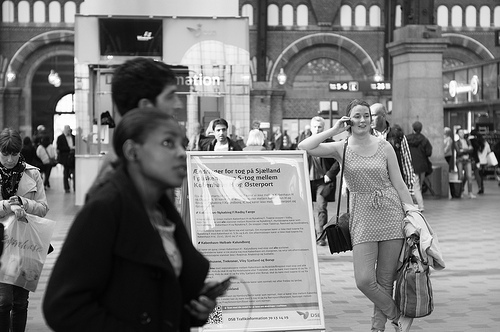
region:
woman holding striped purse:
[368, 222, 454, 329]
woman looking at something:
[99, 128, 199, 328]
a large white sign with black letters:
[236, 146, 329, 329]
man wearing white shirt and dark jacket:
[204, 113, 251, 156]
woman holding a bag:
[0, 133, 55, 260]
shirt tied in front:
[338, 149, 403, 311]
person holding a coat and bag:
[380, 199, 442, 326]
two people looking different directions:
[38, 57, 208, 324]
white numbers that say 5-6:
[305, 75, 354, 101]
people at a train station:
[3, 74, 456, 306]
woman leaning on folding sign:
[321, 110, 428, 320]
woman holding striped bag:
[407, 225, 434, 322]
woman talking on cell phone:
[311, 94, 403, 141]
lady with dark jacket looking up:
[71, 116, 235, 318]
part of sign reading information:
[170, 56, 248, 102]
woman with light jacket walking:
[3, 129, 47, 313]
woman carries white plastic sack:
[4, 189, 56, 292]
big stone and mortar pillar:
[391, 42, 450, 187]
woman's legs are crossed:
[353, 238, 410, 310]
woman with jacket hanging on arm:
[399, 185, 447, 280]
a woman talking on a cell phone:
[292, 97, 392, 154]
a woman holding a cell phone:
[311, 99, 388, 154]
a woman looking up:
[88, 105, 199, 237]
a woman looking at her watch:
[3, 117, 32, 263]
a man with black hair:
[113, 58, 185, 108]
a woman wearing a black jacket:
[58, 105, 203, 319]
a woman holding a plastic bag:
[1, 122, 57, 294]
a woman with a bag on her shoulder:
[311, 95, 373, 265]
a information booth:
[157, 57, 242, 143]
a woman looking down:
[3, 114, 37, 241]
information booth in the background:
[84, 60, 249, 175]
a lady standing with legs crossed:
[297, 97, 447, 328]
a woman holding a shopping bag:
[2, 120, 53, 327]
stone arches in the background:
[5, 17, 499, 145]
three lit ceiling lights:
[1, 3, 74, 95]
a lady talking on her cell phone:
[303, 90, 392, 172]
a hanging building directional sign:
[325, 7, 397, 95]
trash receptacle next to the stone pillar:
[426, 162, 447, 197]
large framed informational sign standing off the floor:
[183, 142, 330, 329]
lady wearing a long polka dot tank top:
[329, 95, 425, 249]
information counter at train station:
[70, 57, 242, 99]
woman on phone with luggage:
[298, 98, 454, 326]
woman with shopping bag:
[0, 121, 55, 327]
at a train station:
[1, 50, 497, 142]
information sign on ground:
[187, 148, 329, 328]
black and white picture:
[1, 50, 496, 310]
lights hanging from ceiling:
[38, 47, 68, 97]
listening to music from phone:
[51, 111, 246, 328]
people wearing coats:
[1, 62, 236, 322]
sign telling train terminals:
[323, 76, 400, 96]